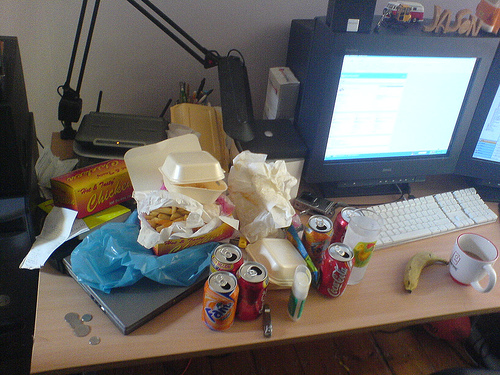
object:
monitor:
[457, 33, 499, 202]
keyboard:
[451, 188, 499, 226]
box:
[51, 158, 128, 218]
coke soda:
[334, 207, 349, 245]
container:
[146, 197, 235, 254]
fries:
[170, 211, 187, 221]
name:
[426, 12, 485, 36]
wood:
[455, 10, 483, 34]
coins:
[89, 336, 100, 345]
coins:
[82, 314, 91, 322]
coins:
[64, 313, 80, 322]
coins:
[70, 321, 82, 328]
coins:
[74, 325, 90, 336]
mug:
[447, 232, 497, 294]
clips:
[245, 284, 300, 366]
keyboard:
[412, 192, 448, 238]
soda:
[306, 215, 331, 258]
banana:
[397, 252, 450, 292]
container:
[159, 152, 227, 203]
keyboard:
[379, 203, 407, 245]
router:
[73, 91, 173, 159]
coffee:
[464, 251, 484, 261]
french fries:
[153, 207, 172, 215]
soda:
[210, 239, 242, 271]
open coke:
[327, 242, 356, 270]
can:
[237, 262, 269, 322]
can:
[203, 271, 239, 332]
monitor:
[306, 33, 500, 193]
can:
[210, 243, 242, 275]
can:
[317, 243, 354, 298]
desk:
[29, 188, 500, 374]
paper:
[132, 191, 205, 211]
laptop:
[63, 256, 206, 332]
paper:
[20, 206, 79, 270]